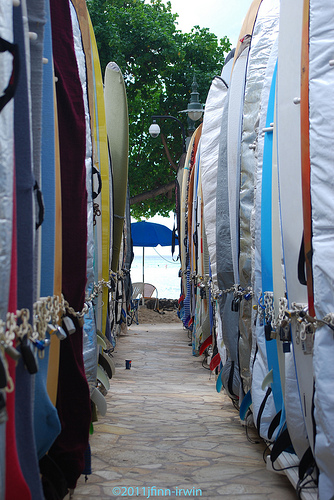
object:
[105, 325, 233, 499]
walkway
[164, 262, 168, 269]
person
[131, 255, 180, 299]
water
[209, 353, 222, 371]
fin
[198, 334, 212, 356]
fin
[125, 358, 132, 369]
cup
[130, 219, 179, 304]
umbrella